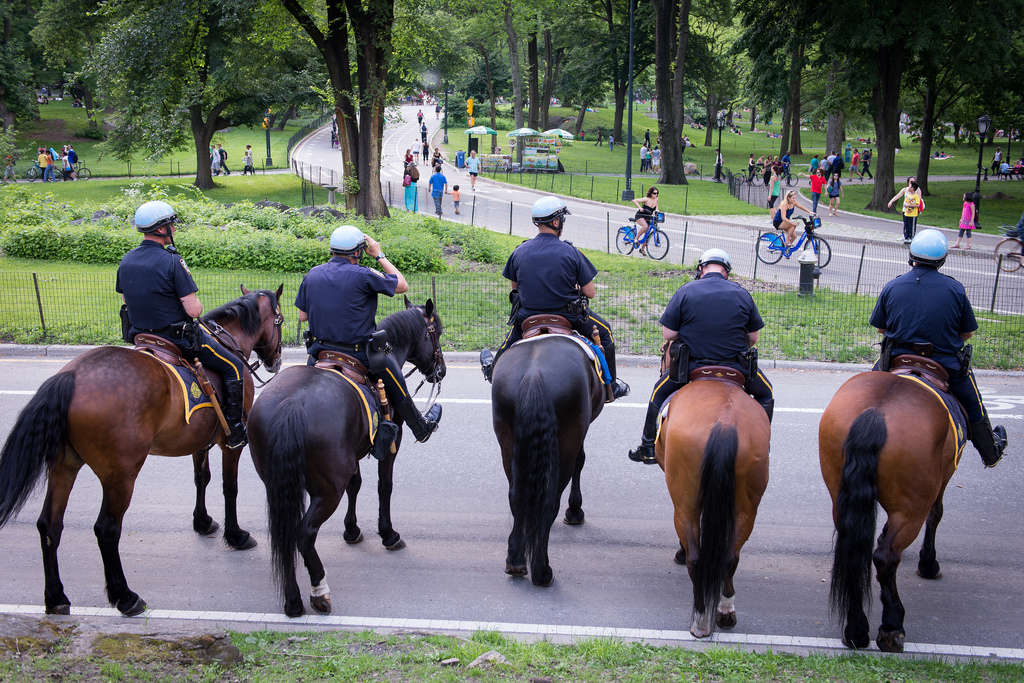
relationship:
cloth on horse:
[142, 336, 250, 417] [0, 276, 286, 625]